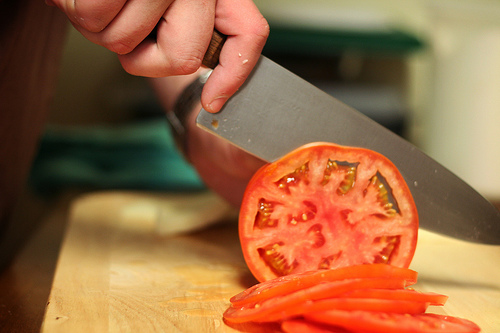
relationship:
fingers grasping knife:
[55, 2, 275, 111] [127, 2, 499, 244]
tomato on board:
[223, 141, 481, 332] [47, 193, 223, 329]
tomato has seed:
[223, 141, 481, 332] [260, 210, 276, 218]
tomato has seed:
[223, 141, 481, 332] [297, 209, 310, 223]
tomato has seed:
[223, 141, 481, 332] [261, 247, 277, 257]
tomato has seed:
[223, 141, 481, 332] [285, 215, 300, 226]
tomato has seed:
[223, 141, 481, 332] [374, 180, 387, 192]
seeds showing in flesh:
[327, 160, 419, 272] [349, 149, 409, 267]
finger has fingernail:
[196, 0, 272, 125] [200, 83, 231, 121]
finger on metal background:
[196, 0, 272, 125] [206, 50, 421, 208]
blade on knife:
[212, 59, 498, 255] [176, 27, 484, 246]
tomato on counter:
[236, 140, 419, 282] [39, 185, 497, 331]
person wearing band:
[51, 3, 273, 204] [168, 63, 217, 162]